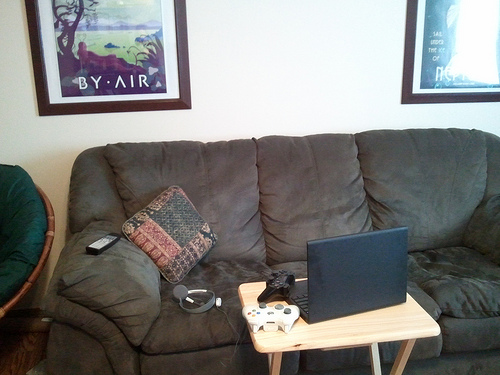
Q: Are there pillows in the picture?
A: Yes, there is a pillow.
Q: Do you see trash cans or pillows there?
A: Yes, there is a pillow.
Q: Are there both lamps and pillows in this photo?
A: No, there is a pillow but no lamps.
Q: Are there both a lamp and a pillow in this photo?
A: No, there is a pillow but no lamps.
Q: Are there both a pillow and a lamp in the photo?
A: No, there is a pillow but no lamps.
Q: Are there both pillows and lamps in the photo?
A: No, there is a pillow but no lamps.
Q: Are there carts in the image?
A: No, there are no carts.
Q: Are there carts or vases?
A: No, there are no carts or vases.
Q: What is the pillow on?
A: The pillow is on the couch.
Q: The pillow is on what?
A: The pillow is on the couch.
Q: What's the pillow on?
A: The pillow is on the couch.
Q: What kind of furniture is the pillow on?
A: The pillow is on the couch.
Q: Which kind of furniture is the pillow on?
A: The pillow is on the couch.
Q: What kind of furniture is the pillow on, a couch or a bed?
A: The pillow is on a couch.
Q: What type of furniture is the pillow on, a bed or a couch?
A: The pillow is on a couch.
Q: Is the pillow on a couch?
A: Yes, the pillow is on a couch.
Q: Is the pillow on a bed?
A: No, the pillow is on a couch.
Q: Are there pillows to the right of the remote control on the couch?
A: Yes, there is a pillow to the right of the remote control.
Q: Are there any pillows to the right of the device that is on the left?
A: Yes, there is a pillow to the right of the remote control.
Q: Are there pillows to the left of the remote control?
A: No, the pillow is to the right of the remote control.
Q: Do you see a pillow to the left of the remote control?
A: No, the pillow is to the right of the remote control.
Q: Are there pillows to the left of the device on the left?
A: No, the pillow is to the right of the remote control.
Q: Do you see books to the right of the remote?
A: No, there is a pillow to the right of the remote.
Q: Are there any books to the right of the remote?
A: No, there is a pillow to the right of the remote.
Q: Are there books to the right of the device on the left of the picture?
A: No, there is a pillow to the right of the remote.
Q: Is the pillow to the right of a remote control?
A: Yes, the pillow is to the right of a remote control.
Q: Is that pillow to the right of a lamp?
A: No, the pillow is to the right of a remote control.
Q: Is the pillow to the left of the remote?
A: No, the pillow is to the right of the remote.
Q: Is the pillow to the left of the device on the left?
A: No, the pillow is to the right of the remote.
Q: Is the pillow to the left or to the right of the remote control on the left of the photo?
A: The pillow is to the right of the remote control.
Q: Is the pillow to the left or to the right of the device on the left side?
A: The pillow is to the right of the remote control.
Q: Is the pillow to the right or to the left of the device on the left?
A: The pillow is to the right of the remote control.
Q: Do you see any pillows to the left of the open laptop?
A: Yes, there is a pillow to the left of the laptop.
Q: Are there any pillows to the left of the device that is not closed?
A: Yes, there is a pillow to the left of the laptop.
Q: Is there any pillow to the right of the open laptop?
A: No, the pillow is to the left of the laptop.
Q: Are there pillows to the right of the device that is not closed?
A: No, the pillow is to the left of the laptop.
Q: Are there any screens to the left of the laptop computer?
A: No, there is a pillow to the left of the laptop computer.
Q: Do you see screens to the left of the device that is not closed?
A: No, there is a pillow to the left of the laptop computer.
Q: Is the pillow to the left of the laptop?
A: Yes, the pillow is to the left of the laptop.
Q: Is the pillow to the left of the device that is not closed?
A: Yes, the pillow is to the left of the laptop.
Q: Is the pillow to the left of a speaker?
A: No, the pillow is to the left of the laptop.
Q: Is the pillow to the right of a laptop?
A: No, the pillow is to the left of a laptop.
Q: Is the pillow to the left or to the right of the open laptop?
A: The pillow is to the left of the laptop.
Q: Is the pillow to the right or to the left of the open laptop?
A: The pillow is to the left of the laptop.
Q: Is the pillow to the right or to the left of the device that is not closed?
A: The pillow is to the left of the laptop.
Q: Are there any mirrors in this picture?
A: No, there are no mirrors.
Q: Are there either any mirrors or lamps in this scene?
A: No, there are no mirrors or lamps.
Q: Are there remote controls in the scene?
A: Yes, there is a remote control.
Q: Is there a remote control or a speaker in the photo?
A: Yes, there is a remote control.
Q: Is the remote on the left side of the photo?
A: Yes, the remote is on the left of the image.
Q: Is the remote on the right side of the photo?
A: No, the remote is on the left of the image.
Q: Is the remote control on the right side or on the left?
A: The remote control is on the left of the image.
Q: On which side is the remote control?
A: The remote control is on the left of the image.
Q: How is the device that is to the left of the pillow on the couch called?
A: The device is a remote control.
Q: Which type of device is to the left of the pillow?
A: The device is a remote control.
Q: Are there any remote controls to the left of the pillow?
A: Yes, there is a remote control to the left of the pillow.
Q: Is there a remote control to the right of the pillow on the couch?
A: No, the remote control is to the left of the pillow.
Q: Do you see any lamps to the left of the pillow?
A: No, there is a remote control to the left of the pillow.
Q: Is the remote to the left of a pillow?
A: Yes, the remote is to the left of a pillow.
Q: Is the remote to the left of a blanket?
A: No, the remote is to the left of a pillow.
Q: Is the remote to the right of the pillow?
A: No, the remote is to the left of the pillow.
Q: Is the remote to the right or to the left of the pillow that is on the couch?
A: The remote is to the left of the pillow.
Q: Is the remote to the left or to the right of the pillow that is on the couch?
A: The remote is to the left of the pillow.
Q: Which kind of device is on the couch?
A: The device is a remote control.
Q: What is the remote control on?
A: The remote control is on the couch.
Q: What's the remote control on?
A: The remote control is on the couch.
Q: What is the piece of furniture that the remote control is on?
A: The piece of furniture is a couch.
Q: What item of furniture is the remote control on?
A: The remote control is on the couch.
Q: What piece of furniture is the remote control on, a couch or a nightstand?
A: The remote control is on a couch.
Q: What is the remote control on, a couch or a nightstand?
A: The remote control is on a couch.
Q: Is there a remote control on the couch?
A: Yes, there is a remote control on the couch.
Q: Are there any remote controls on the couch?
A: Yes, there is a remote control on the couch.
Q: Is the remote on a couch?
A: Yes, the remote is on a couch.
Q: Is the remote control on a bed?
A: No, the remote control is on a couch.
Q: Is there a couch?
A: Yes, there is a couch.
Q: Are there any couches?
A: Yes, there is a couch.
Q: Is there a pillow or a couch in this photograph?
A: Yes, there is a couch.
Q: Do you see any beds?
A: No, there are no beds.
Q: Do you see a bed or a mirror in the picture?
A: No, there are no beds or mirrors.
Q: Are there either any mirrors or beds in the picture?
A: No, there are no beds or mirrors.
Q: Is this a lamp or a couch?
A: This is a couch.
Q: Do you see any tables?
A: Yes, there is a table.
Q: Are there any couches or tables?
A: Yes, there is a table.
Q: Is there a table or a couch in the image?
A: Yes, there is a table.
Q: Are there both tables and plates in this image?
A: No, there is a table but no plates.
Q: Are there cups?
A: No, there are no cups.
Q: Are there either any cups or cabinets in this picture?
A: No, there are no cups or cabinets.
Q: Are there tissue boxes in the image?
A: No, there are no tissue boxes.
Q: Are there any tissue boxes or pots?
A: No, there are no tissue boxes or pots.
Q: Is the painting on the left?
A: Yes, the painting is on the left of the image.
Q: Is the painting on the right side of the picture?
A: No, the painting is on the left of the image.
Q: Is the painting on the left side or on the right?
A: The painting is on the left of the image.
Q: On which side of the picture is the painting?
A: The painting is on the left of the image.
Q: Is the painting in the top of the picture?
A: Yes, the painting is in the top of the image.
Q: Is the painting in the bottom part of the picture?
A: No, the painting is in the top of the image.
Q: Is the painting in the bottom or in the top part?
A: The painting is in the top of the image.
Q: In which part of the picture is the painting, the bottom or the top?
A: The painting is in the top of the image.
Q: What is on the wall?
A: The painting is on the wall.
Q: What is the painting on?
A: The painting is on the wall.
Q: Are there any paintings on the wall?
A: Yes, there is a painting on the wall.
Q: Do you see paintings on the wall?
A: Yes, there is a painting on the wall.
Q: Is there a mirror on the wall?
A: No, there is a painting on the wall.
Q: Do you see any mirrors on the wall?
A: No, there is a painting on the wall.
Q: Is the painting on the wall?
A: Yes, the painting is on the wall.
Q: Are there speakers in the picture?
A: No, there are no speakers.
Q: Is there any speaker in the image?
A: No, there are no speakers.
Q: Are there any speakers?
A: No, there are no speakers.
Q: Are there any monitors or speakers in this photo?
A: No, there are no speakers or monitors.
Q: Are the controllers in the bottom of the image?
A: Yes, the controllers are in the bottom of the image.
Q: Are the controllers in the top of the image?
A: No, the controllers are in the bottom of the image.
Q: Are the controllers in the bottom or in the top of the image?
A: The controllers are in the bottom of the image.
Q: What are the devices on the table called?
A: The devices are controllers.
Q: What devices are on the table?
A: The devices are controllers.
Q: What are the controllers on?
A: The controllers are on the table.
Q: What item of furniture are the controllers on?
A: The controllers are on the table.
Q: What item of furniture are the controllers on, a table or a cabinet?
A: The controllers are on a table.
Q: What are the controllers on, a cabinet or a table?
A: The controllers are on a table.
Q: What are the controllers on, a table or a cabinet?
A: The controllers are on a table.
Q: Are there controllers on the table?
A: Yes, there are controllers on the table.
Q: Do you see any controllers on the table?
A: Yes, there are controllers on the table.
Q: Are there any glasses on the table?
A: No, there are controllers on the table.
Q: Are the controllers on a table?
A: Yes, the controllers are on a table.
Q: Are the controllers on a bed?
A: No, the controllers are on a table.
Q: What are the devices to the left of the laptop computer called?
A: The devices are controllers.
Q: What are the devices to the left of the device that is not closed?
A: The devices are controllers.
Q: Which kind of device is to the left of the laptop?
A: The devices are controllers.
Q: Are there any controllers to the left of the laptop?
A: Yes, there are controllers to the left of the laptop.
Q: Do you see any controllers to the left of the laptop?
A: Yes, there are controllers to the left of the laptop.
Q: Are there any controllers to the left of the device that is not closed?
A: Yes, there are controllers to the left of the laptop.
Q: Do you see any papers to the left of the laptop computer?
A: No, there are controllers to the left of the laptop computer.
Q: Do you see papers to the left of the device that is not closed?
A: No, there are controllers to the left of the laptop computer.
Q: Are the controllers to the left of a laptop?
A: Yes, the controllers are to the left of a laptop.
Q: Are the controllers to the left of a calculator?
A: No, the controllers are to the left of a laptop.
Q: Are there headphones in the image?
A: Yes, there are headphones.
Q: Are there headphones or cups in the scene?
A: Yes, there are headphones.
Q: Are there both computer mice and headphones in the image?
A: No, there are headphones but no computer mice.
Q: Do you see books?
A: No, there are no books.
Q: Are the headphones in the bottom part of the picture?
A: Yes, the headphones are in the bottom of the image.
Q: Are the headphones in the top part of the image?
A: No, the headphones are in the bottom of the image.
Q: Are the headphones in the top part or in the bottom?
A: The headphones are in the bottom of the image.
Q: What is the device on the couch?
A: The device is headphones.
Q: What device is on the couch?
A: The device is headphones.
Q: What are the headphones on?
A: The headphones are on the couch.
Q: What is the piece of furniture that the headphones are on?
A: The piece of furniture is a couch.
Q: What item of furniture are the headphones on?
A: The headphones are on the couch.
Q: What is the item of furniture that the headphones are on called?
A: The piece of furniture is a couch.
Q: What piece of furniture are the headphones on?
A: The headphones are on the couch.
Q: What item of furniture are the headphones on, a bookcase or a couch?
A: The headphones are on a couch.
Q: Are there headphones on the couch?
A: Yes, there are headphones on the couch.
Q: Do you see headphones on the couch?
A: Yes, there are headphones on the couch.